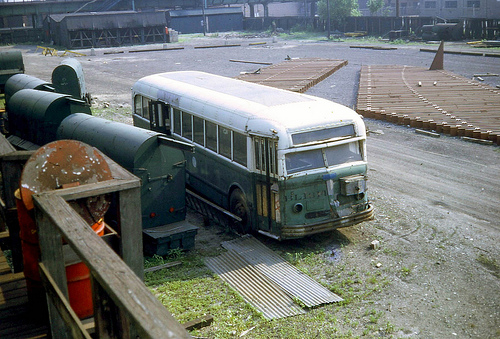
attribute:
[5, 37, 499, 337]
track — dirt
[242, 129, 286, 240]
door — closed